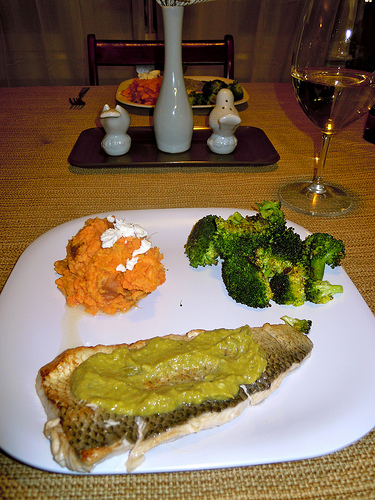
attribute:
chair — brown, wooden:
[75, 29, 247, 79]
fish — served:
[31, 320, 316, 475]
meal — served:
[33, 194, 355, 477]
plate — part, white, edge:
[1, 198, 373, 480]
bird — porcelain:
[205, 85, 250, 178]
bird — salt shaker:
[208, 88, 242, 154]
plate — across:
[114, 73, 249, 109]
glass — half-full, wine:
[279, 3, 374, 218]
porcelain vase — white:
[151, 5, 194, 152]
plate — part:
[274, 389, 305, 436]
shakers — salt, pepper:
[90, 79, 241, 159]